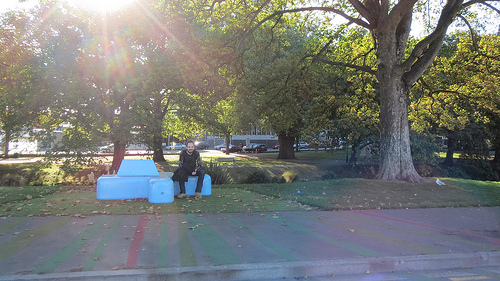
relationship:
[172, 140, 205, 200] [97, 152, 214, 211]
man on bench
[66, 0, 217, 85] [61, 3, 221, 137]
sun shining through trees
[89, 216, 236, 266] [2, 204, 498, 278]
colored stripes on sidewalk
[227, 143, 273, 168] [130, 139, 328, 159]
car on parking lot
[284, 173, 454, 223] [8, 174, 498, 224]
leaves on ground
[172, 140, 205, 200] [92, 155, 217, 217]
man on bench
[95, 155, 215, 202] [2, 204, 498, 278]
blue structure on sidewalk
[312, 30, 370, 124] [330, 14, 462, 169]
leaves on tree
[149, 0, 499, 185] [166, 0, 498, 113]
large tree with branches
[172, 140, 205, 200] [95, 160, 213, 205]
man on structure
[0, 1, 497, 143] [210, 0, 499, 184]
leaves on large tree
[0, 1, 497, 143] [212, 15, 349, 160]
leaves on tree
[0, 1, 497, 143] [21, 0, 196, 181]
leaves on tree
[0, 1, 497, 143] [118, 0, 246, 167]
leaves on tree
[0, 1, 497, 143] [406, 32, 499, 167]
leaves on tree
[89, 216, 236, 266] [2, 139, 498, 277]
colored stripes on ground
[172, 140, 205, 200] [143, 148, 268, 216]
man sitting on bench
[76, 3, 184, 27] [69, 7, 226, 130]
sun shining through branches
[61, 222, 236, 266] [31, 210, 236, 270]
colored stripes on sidewalk